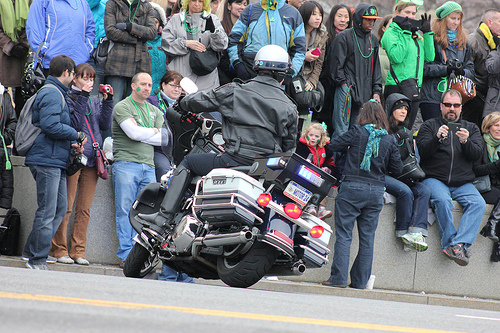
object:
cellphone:
[447, 122, 462, 132]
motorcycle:
[121, 75, 340, 289]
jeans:
[420, 179, 487, 249]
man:
[111, 72, 169, 269]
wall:
[10, 155, 500, 302]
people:
[49, 61, 114, 267]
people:
[321, 99, 404, 290]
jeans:
[21, 164, 68, 266]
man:
[21, 53, 89, 270]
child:
[296, 120, 336, 220]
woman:
[379, 0, 436, 131]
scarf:
[391, 14, 423, 36]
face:
[399, 4, 415, 19]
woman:
[418, 0, 474, 122]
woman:
[298, 0, 329, 129]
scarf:
[358, 123, 389, 173]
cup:
[364, 275, 376, 290]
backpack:
[19, 61, 46, 103]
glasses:
[67, 71, 76, 77]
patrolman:
[131, 42, 299, 237]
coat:
[103, 0, 158, 78]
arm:
[102, 0, 138, 44]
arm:
[126, 3, 159, 41]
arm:
[112, 103, 157, 143]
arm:
[141, 110, 170, 147]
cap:
[433, 0, 463, 19]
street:
[0, 264, 500, 333]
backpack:
[11, 82, 67, 156]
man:
[416, 87, 486, 267]